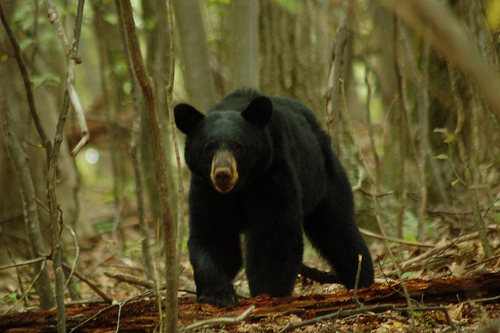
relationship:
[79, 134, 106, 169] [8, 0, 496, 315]
glare in trees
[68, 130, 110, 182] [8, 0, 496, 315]
camera glare in trees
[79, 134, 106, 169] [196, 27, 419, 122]
glare in trees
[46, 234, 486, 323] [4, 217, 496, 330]
twigs on ground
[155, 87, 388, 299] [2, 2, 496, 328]
bear facing camera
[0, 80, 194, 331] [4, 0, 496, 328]
weeds in field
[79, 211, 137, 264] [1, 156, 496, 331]
leaves on ground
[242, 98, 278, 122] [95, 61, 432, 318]
ear of bear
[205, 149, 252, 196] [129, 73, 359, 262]
nose of bear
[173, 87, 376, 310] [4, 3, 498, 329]
bear walking in woods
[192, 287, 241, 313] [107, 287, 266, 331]
claws on tree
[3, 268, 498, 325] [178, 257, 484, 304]
log laying on ground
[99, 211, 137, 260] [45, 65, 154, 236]
leaves on branch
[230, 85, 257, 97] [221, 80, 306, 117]
fur standing up on back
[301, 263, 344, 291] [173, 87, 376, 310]
branch under bear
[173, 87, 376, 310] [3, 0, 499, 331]
bear walking in forest